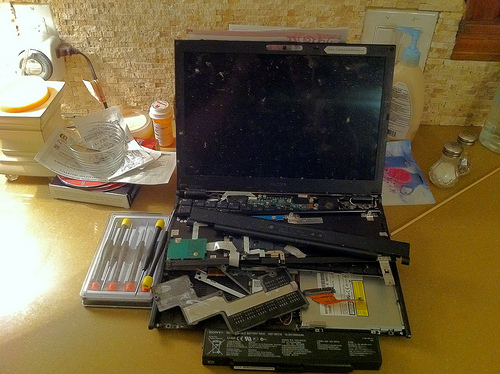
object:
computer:
[147, 37, 407, 336]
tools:
[123, 222, 148, 292]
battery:
[200, 327, 384, 371]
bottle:
[387, 24, 425, 145]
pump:
[399, 24, 424, 71]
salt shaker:
[426, 144, 467, 188]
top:
[442, 141, 464, 159]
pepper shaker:
[428, 144, 462, 189]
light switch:
[368, 10, 400, 43]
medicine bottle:
[147, 97, 174, 145]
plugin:
[41, 37, 74, 92]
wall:
[96, 4, 161, 61]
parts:
[207, 238, 247, 266]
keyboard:
[174, 192, 315, 217]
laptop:
[158, 27, 421, 330]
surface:
[427, 234, 489, 367]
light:
[0, 223, 46, 293]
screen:
[184, 55, 378, 177]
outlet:
[27, 14, 57, 49]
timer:
[15, 47, 54, 80]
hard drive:
[228, 279, 307, 335]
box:
[84, 211, 168, 300]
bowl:
[66, 120, 129, 177]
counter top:
[411, 213, 495, 372]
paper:
[385, 140, 436, 205]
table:
[0, 205, 79, 279]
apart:
[185, 186, 273, 230]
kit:
[77, 211, 175, 305]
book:
[46, 183, 136, 209]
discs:
[56, 174, 107, 186]